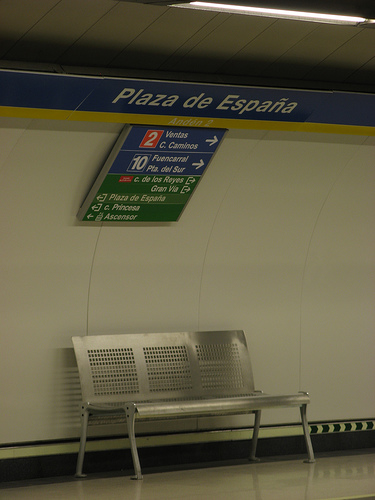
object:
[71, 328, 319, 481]
bench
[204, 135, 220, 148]
arrow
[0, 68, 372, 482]
wall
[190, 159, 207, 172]
arrow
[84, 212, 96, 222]
arrow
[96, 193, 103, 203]
arrow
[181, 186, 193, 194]
arrow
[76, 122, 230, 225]
sign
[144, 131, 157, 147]
two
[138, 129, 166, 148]
square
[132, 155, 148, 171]
ten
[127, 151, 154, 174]
square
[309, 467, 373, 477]
reflection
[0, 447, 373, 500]
floor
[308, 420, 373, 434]
arrows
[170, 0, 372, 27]
light fixture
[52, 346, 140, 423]
shadow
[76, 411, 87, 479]
leg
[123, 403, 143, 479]
leg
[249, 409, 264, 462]
leg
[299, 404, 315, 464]
leg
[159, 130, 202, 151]
writing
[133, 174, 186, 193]
writing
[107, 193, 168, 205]
writing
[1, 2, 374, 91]
ceiling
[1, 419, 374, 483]
molding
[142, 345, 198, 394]
section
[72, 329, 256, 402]
back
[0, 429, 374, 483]
stripe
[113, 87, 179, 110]
plaza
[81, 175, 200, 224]
portion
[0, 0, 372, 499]
station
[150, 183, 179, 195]
gran via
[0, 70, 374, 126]
stripe